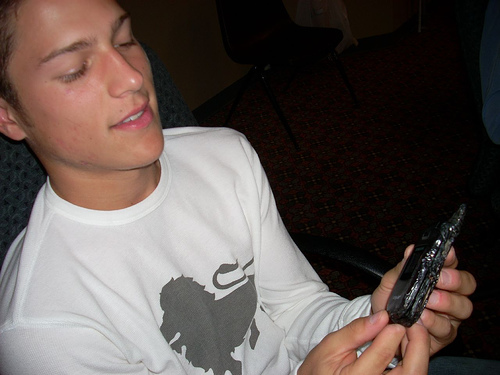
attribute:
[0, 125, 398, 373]
shirt — white, long sleeve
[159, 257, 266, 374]
lion — gray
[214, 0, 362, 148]
chair — black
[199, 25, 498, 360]
carpet — dark, patterned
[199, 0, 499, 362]
ground — red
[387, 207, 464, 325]
phone — burnt, melted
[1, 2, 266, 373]
boy — looking down